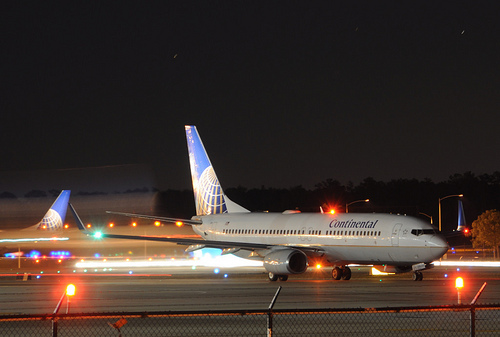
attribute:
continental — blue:
[328, 217, 380, 229]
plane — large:
[68, 123, 452, 282]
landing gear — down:
[408, 265, 426, 283]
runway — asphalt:
[1, 266, 499, 335]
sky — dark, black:
[1, 1, 499, 190]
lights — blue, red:
[6, 249, 76, 265]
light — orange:
[63, 281, 78, 314]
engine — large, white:
[263, 247, 310, 276]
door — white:
[390, 221, 403, 248]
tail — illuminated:
[183, 123, 243, 214]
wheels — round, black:
[330, 266, 352, 280]